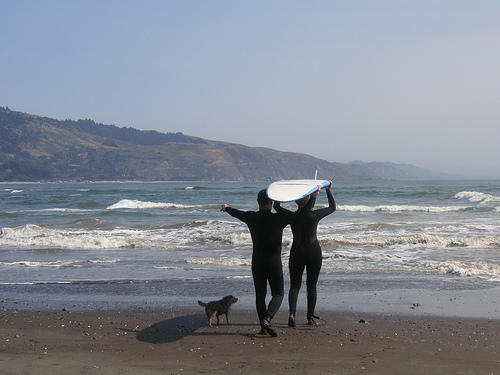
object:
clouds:
[250, 14, 447, 159]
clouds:
[457, 56, 497, 172]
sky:
[15, 9, 485, 124]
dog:
[193, 292, 241, 327]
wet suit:
[273, 189, 337, 315]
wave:
[411, 190, 497, 229]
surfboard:
[264, 176, 332, 205]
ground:
[0, 326, 499, 357]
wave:
[412, 252, 498, 287]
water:
[5, 175, 499, 287]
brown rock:
[354, 317, 370, 326]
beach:
[1, 276, 498, 372]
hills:
[0, 107, 498, 181]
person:
[274, 184, 337, 326]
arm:
[221, 195, 252, 224]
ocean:
[0, 179, 498, 289]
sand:
[161, 315, 365, 373]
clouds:
[180, 59, 390, 142]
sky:
[56, 3, 445, 168]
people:
[219, 186, 323, 337]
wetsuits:
[225, 197, 317, 320]